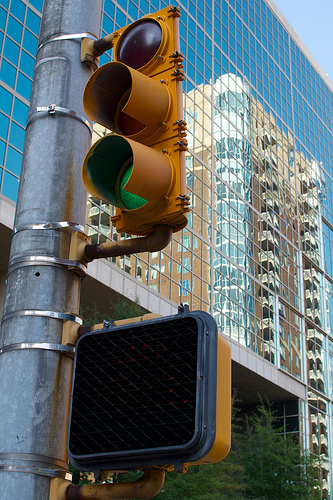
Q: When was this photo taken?
A: Day time.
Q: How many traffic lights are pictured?
A: One.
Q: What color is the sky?
A: Blue.